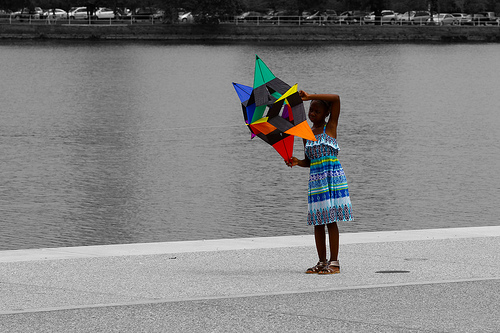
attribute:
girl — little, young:
[279, 87, 354, 277]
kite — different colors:
[232, 65, 327, 169]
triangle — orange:
[283, 120, 321, 145]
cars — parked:
[6, 2, 498, 27]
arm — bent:
[312, 92, 341, 138]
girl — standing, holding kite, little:
[285, 82, 353, 283]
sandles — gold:
[303, 255, 343, 276]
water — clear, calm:
[1, 33, 496, 243]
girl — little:
[233, 62, 395, 266]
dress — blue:
[298, 124, 353, 231]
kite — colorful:
[216, 48, 311, 179]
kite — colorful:
[229, 55, 324, 180]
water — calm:
[13, 47, 489, 214]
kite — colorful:
[205, 37, 342, 167]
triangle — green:
[252, 52, 275, 88]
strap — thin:
[320, 119, 331, 134]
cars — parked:
[428, 13, 464, 25]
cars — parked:
[396, 8, 431, 23]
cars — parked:
[363, 7, 400, 22]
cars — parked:
[334, 7, 365, 22]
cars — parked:
[302, 8, 335, 21]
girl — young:
[237, 67, 401, 294]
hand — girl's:
[282, 156, 299, 166]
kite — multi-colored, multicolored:
[232, 53, 319, 167]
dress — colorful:
[302, 117, 352, 227]